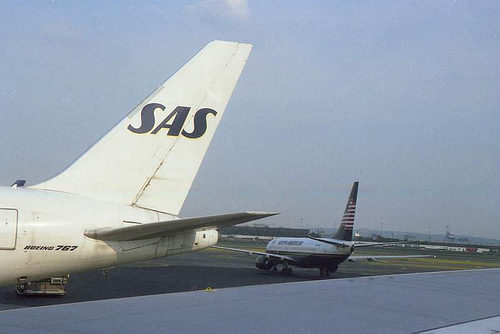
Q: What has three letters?
A: Plane tail.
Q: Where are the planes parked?
A: Tarmac.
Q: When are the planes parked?
A: Sunny day.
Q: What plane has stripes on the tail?
A: Plane farther away.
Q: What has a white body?
A: Closest plane.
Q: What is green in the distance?
A: Grass.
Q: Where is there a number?
A: Closest plane body.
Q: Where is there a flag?
A: Plane tail.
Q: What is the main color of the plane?
A: White.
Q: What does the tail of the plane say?
A: SAS.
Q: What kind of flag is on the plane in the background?
A: American flag.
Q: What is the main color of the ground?
A: Gray.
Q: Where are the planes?
A: Runway.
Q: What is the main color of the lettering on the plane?
A: Blue.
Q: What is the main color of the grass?
A: Green.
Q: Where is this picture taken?
A: Airport.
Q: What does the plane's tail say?
A: SAS.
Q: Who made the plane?
A: Boeing.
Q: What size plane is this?
A: 767.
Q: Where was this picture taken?
A: Airport.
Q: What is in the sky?
A: Clouds.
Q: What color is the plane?
A: White.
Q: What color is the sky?
A: Blue.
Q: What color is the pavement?
A: Black.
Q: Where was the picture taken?
A: The airport.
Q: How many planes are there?
A: Two.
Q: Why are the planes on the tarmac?
A: To land.